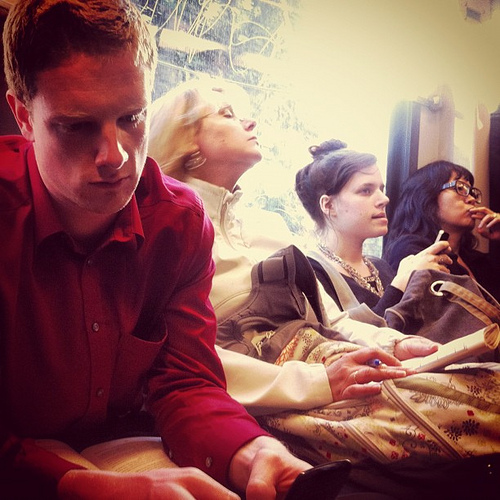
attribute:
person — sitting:
[136, 65, 496, 490]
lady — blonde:
[148, 75, 499, 490]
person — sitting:
[2, 1, 307, 499]